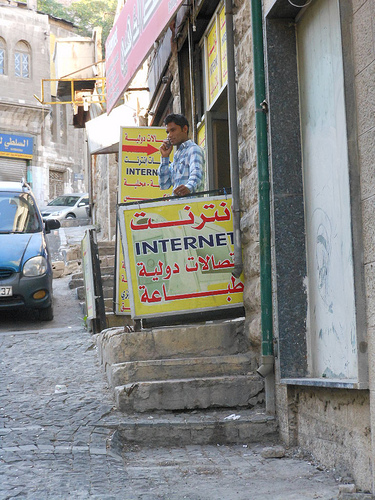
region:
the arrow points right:
[127, 141, 157, 159]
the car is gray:
[45, 189, 85, 227]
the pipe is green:
[257, 3, 269, 353]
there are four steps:
[117, 333, 257, 434]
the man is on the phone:
[162, 134, 176, 155]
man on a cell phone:
[155, 112, 210, 203]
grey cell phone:
[163, 134, 172, 150]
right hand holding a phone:
[154, 138, 175, 159]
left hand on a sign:
[173, 181, 191, 199]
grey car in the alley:
[2, 175, 61, 325]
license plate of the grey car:
[0, 281, 15, 298]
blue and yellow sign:
[0, 128, 36, 161]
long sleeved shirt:
[153, 140, 203, 196]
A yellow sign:
[104, 203, 241, 321]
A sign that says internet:
[112, 193, 243, 316]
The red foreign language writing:
[126, 251, 251, 302]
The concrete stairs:
[96, 319, 276, 452]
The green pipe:
[241, 3, 293, 409]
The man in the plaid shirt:
[144, 115, 208, 199]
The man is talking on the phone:
[143, 109, 206, 192]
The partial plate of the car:
[0, 284, 16, 297]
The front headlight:
[20, 250, 57, 279]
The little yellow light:
[24, 282, 55, 304]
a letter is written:
[133, 240, 144, 260]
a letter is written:
[141, 238, 160, 254]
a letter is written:
[156, 235, 171, 254]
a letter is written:
[170, 235, 182, 252]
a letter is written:
[184, 234, 197, 251]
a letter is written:
[196, 231, 219, 255]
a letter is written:
[214, 230, 230, 247]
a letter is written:
[226, 230, 237, 250]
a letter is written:
[132, 239, 139, 255]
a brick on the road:
[70, 435, 85, 453]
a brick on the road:
[80, 437, 98, 459]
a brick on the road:
[47, 430, 72, 447]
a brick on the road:
[57, 380, 63, 400]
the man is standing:
[159, 113, 203, 194]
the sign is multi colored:
[117, 191, 246, 319]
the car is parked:
[0, 180, 54, 321]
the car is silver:
[36, 192, 88, 221]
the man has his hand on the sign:
[117, 112, 243, 320]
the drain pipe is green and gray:
[249, 0, 274, 376]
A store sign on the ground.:
[117, 188, 242, 320]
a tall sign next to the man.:
[115, 121, 179, 312]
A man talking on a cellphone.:
[151, 112, 204, 199]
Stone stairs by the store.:
[104, 320, 266, 442]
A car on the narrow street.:
[0, 179, 62, 325]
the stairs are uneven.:
[105, 321, 301, 452]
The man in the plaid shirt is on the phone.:
[152, 114, 208, 198]